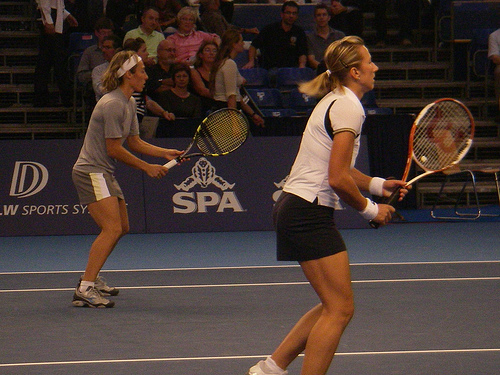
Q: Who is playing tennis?
A: Two women.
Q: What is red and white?
A: The tennis racket.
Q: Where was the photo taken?
A: At a court.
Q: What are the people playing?
A: Tennis.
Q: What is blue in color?
A: Court.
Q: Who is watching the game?
A: Some people.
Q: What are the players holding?
A: Rackets.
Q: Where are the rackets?
A: In hands of players.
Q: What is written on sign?
A: Spa.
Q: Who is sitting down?
A: The crowd.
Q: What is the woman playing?
A: Tennis.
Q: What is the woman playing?
A: Tennis.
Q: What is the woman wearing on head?
A: A white headband.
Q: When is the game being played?
A: At night.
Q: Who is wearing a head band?
A: Woman on left.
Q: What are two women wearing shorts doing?
A: Playing tennis.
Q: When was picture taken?
A: During tennis match.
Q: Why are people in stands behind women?
A: Watching tennis players.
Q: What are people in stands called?
A: Spectators.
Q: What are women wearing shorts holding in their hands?
A: Tennis racquet.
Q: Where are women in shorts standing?
A: On tennis court.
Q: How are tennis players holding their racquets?
A: In both hands.